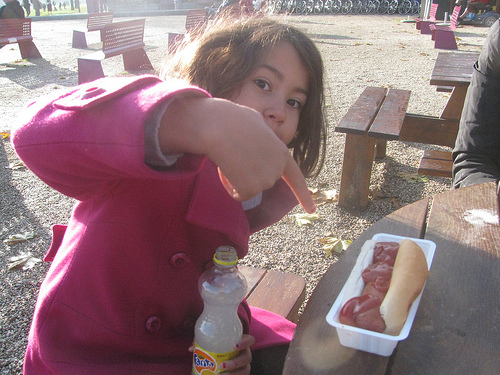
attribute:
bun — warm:
[337, 238, 432, 336]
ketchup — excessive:
[341, 241, 397, 321]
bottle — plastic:
[191, 245, 248, 374]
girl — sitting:
[11, 16, 328, 374]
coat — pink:
[14, 75, 312, 374]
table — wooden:
[284, 180, 499, 374]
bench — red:
[77, 18, 155, 88]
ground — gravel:
[224, 14, 499, 318]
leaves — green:
[320, 235, 354, 260]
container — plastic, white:
[324, 233, 438, 359]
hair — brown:
[154, 12, 329, 181]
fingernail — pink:
[307, 205, 318, 214]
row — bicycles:
[255, 0, 422, 15]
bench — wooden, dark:
[335, 52, 484, 212]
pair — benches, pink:
[414, 2, 462, 50]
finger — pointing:
[283, 149, 317, 215]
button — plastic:
[144, 316, 163, 334]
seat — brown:
[334, 86, 412, 213]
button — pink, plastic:
[169, 251, 190, 271]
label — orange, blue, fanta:
[192, 343, 218, 374]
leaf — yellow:
[398, 169, 428, 185]